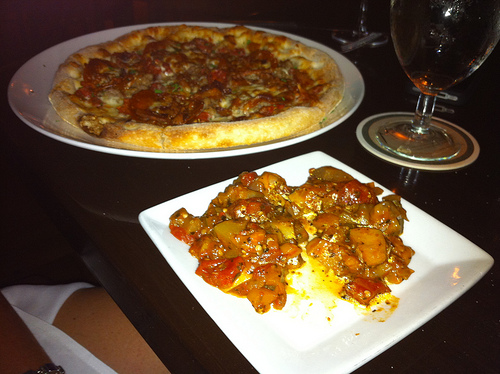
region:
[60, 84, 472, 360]
the plate is white and visible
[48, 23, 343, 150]
Pizza on a plate.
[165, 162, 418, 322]
Food on a square plate.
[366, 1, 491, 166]
Stemmed glass on the table.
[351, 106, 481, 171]
Coaster for the glass.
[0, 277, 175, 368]
Napkin folded on the table.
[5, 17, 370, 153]
White rounded plate on table.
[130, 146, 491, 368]
Square white plate on table.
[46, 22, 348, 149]
Browned pizza with no pieces taken.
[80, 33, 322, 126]
Pizza sauce on the pizza.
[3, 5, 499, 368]
Dining table on which the food and plates sit.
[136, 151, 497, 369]
a plate of food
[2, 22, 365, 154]
a plate of food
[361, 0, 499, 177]
a glass of wine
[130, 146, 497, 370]
the plate is white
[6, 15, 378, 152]
the plate is white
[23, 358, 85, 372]
the person is wearing a wrist watch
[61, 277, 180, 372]
the thigh of a person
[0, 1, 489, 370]
a well laid table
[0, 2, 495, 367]
the table is brown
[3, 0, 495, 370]
one person at the table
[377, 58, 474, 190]
Wine glass sitting on table.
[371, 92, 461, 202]
Wine glass is on top of a beverage coaster.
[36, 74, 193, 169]
Pizza on top of white plate.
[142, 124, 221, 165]
Golden brown crust on pizza.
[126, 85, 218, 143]
White cheese melted on pizza.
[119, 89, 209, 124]
Red sauce on pizza.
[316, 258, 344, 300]
Yellow sauce on plate.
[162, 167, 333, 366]
Food on top of square plate.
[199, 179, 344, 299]
Square plate is white in color.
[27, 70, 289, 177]
Pizza is on round plate.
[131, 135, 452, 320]
plate filled with food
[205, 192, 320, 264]
multi colored food on a plate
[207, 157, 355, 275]
yellow food on a plate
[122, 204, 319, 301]
red food on a plate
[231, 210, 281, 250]
green vegetables on plate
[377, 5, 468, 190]
glass of wine next to food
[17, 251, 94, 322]
napkin on lap of person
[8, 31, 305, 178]
small pizza on a plate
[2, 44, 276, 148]
pizza filled with vegetables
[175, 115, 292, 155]
golden brown crust of pizza